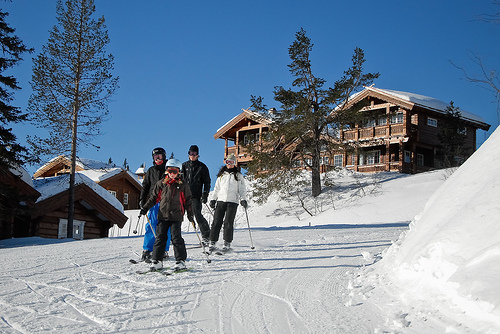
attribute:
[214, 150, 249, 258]
skier — sking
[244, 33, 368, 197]
tree — large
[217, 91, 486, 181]
building — brown, large, built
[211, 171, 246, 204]
jacket — white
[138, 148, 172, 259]
skier — young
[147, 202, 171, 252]
pants — blue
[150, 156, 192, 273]
skier — young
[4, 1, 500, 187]
sky — clear, blue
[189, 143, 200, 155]
cap — black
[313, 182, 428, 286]
snow — white, small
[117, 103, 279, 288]
people — skiing, in a group